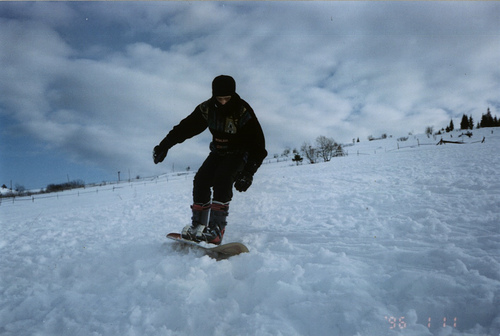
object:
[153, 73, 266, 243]
person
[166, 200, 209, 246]
boots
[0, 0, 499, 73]
clouds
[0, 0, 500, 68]
sky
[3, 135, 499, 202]
fence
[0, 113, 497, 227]
background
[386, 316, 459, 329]
date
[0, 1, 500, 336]
picture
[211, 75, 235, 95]
hat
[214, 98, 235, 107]
ski mask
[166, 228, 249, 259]
snowboard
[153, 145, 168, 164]
glove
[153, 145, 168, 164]
hand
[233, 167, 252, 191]
hand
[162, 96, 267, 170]
jacket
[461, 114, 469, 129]
trees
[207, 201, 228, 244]
boot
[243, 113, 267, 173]
arm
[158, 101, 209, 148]
arm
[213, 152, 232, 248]
leg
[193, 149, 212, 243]
leg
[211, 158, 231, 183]
black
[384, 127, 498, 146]
top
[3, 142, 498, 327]
snow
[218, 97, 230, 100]
eyes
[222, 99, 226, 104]
nose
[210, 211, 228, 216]
straps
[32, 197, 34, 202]
posts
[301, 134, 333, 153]
branches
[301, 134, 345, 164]
bushes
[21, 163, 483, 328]
place